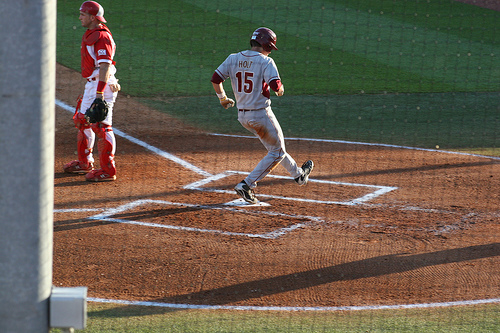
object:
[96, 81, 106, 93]
sweatband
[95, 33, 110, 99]
arm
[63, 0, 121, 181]
baseball catcher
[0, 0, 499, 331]
baseball field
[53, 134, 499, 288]
dirt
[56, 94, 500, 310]
diamond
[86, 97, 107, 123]
baseball mitt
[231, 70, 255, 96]
number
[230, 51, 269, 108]
back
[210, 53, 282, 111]
jersey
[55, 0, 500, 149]
grass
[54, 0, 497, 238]
infield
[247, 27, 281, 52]
helmet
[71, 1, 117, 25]
helmet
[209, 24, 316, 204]
player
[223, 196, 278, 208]
plate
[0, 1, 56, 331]
pole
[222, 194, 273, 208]
bases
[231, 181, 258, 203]
foot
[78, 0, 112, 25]
hat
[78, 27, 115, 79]
red shirt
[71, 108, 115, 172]
shin pads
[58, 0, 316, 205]
action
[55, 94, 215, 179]
sideline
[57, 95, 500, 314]
marks